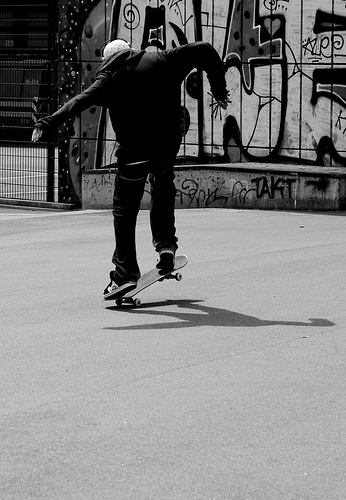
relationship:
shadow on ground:
[105, 299, 337, 340] [0, 201, 345, 438]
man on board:
[27, 37, 257, 273] [103, 249, 202, 306]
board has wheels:
[103, 249, 202, 306] [115, 271, 184, 311]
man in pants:
[27, 37, 257, 273] [106, 143, 180, 258]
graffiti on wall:
[82, 6, 328, 153] [59, 1, 344, 213]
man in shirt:
[27, 37, 257, 273] [66, 40, 226, 159]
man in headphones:
[27, 37, 257, 273] [93, 36, 138, 63]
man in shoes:
[27, 37, 257, 273] [99, 248, 176, 296]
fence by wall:
[2, 0, 83, 208] [59, 1, 344, 213]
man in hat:
[27, 37, 257, 273] [104, 41, 125, 55]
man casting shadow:
[27, 37, 257, 273] [105, 299, 337, 340]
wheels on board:
[115, 271, 184, 311] [103, 249, 202, 306]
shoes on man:
[99, 248, 176, 296] [27, 37, 257, 273]